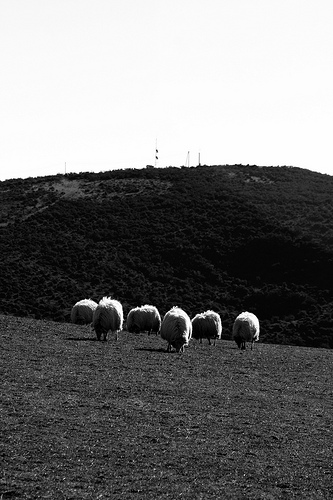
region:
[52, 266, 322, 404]
Sheep herding in a field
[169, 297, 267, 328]
Sheep herding in a field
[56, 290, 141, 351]
Sheep herding in a field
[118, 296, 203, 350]
Sheep herding in a field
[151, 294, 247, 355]
Sheep herding in a field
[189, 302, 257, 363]
Sheep herding in a field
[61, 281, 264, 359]
sheeps on grass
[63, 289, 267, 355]
six sheeps side by side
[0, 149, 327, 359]
a mountain behind six sheeps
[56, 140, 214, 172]
poles on top of mountain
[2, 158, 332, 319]
mountain has dense vegetation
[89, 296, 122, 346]
sheep eats grass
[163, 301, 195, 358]
sheep eats grass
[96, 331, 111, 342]
front feet of sheeps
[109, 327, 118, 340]
back feet of sheeps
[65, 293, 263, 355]
fur of sheeps are long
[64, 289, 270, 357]
group of sheep grazing in field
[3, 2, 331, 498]
black and white photo of sheep in field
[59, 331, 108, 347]
shadow of sheep on grass field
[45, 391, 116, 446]
patch of grass on field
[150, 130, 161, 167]
metal structure on top of hill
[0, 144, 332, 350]
hill top formation before grass field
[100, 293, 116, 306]
white fur on top of sheep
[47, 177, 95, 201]
bald dirt spot on hill top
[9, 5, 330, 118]
white cloudless sky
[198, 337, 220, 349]
three sheep feet in field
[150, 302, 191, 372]
the sheep is eating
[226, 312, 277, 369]
the sheep is eating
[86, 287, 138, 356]
the sheep is eating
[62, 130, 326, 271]
a hill in the distance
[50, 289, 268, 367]
six sheep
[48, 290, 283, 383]
The sheep are grazing.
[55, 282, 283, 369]
The sheep are white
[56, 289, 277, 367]
The sheep are eating grass.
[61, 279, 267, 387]
The sheep are standing.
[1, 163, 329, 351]
The hill is in the background.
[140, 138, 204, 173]
The towers are on the hill.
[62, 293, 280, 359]
The sheep are standing still.